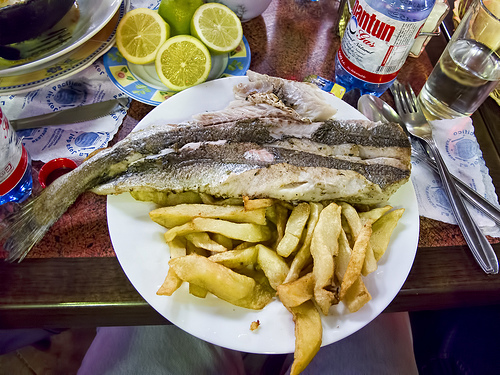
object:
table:
[37, 242, 113, 307]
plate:
[202, 86, 224, 106]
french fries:
[149, 199, 403, 369]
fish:
[0, 69, 412, 261]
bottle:
[335, 0, 433, 95]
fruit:
[116, 0, 243, 90]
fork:
[394, 83, 500, 274]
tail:
[0, 196, 52, 264]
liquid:
[417, 40, 500, 122]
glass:
[416, 0, 498, 122]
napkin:
[409, 116, 499, 238]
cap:
[37, 158, 76, 189]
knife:
[7, 99, 119, 131]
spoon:
[357, 94, 500, 227]